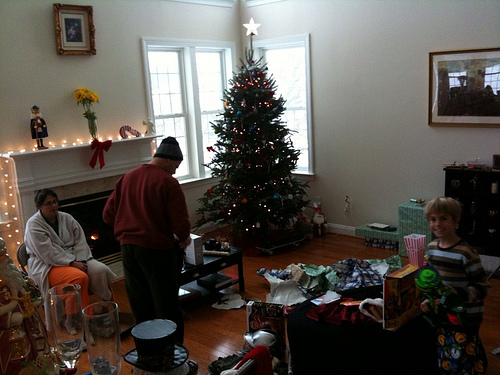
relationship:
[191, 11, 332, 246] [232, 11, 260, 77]
christmas tree in corner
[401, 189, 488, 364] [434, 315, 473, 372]
boy wearing pajamas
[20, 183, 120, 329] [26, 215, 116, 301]
woman in a robe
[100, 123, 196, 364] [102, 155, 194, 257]
man in a sweater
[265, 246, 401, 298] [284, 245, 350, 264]
wrapping paper on floor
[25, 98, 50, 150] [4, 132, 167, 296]
nutcracker doll on fire place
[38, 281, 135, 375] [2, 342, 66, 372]
empty glasses in corner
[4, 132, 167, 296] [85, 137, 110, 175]
fire place with red bow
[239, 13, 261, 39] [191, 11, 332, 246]
star on a christmas tree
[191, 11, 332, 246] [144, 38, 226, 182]
christmas tree next to window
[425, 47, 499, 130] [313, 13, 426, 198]
picture on a wall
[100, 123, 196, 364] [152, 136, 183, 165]
man wearing a hat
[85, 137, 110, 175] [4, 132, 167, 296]
bow on a fire place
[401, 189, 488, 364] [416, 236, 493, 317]
boy wearing a stripe shirt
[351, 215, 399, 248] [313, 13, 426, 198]
present next to wall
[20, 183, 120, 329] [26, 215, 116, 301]
woman wearing a robe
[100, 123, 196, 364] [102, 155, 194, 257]
man wearing a maroon shirt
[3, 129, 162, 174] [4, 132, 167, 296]
christmas lights on fire place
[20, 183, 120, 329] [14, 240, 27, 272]
woman on a chair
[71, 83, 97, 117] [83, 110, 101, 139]
flowers in a vase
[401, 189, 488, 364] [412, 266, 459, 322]
child holding toy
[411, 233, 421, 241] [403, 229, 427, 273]
popcorn in container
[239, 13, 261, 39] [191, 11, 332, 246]
star on top of christmas tree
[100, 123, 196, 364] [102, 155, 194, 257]
man wearing a sweater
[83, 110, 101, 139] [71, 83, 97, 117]
vase of sunflowers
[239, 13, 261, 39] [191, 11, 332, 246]
star on tree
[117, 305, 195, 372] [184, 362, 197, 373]
top hat on table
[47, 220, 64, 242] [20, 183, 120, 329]
sweater on woman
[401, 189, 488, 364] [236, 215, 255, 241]
kid looking at camera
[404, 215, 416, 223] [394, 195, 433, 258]
paper on gifts